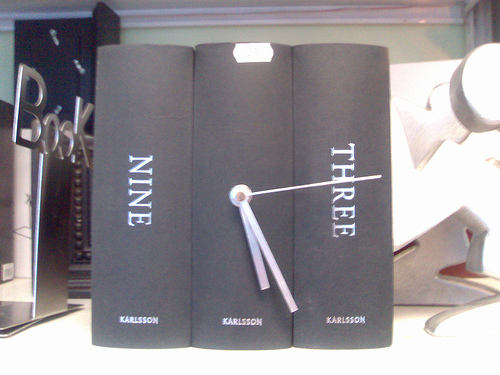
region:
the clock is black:
[75, 44, 402, 374]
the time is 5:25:
[213, 168, 388, 321]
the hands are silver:
[225, 151, 375, 311]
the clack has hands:
[210, 170, 380, 315]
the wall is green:
[391, 32, 447, 49]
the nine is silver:
[115, 145, 165, 237]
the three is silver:
[315, 132, 360, 239]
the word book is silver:
[10, 56, 96, 176]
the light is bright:
[433, 20, 493, 191]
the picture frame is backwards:
[10, 12, 98, 78]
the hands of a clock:
[233, 167, 388, 322]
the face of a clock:
[80, 34, 405, 356]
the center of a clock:
[224, 182, 256, 209]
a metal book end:
[0, 64, 105, 349]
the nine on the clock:
[120, 145, 165, 244]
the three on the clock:
[325, 134, 361, 246]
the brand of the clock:
[215, 310, 270, 332]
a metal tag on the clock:
[227, 39, 278, 66]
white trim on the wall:
[0, 5, 468, 37]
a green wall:
[1, 19, 467, 110]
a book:
[64, 61, 374, 347]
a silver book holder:
[7, 55, 90, 325]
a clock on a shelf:
[70, 0, 400, 349]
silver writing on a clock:
[124, 137, 170, 249]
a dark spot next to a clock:
[402, 185, 488, 336]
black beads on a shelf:
[61, 124, 103, 286]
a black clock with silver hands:
[70, 39, 429, 356]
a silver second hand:
[245, 158, 385, 221]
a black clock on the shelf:
[78, 20, 420, 362]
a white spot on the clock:
[227, 35, 302, 77]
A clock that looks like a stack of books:
[48, 36, 402, 353]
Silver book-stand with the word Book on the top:
[0, 63, 85, 328]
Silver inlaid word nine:
[101, 139, 166, 240]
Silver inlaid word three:
[318, 134, 368, 253]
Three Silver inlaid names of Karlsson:
[106, 299, 391, 337]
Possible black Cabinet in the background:
[8, 10, 104, 102]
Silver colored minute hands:
[192, 108, 389, 314]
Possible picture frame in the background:
[74, 148, 87, 295]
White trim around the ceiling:
[120, 0, 465, 29]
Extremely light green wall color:
[366, 29, 460, 50]